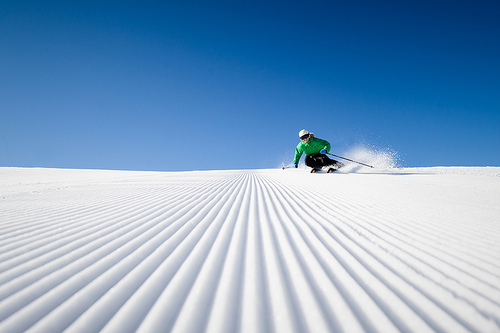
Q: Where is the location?
A: Hillside.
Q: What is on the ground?
A: Snow.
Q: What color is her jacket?
A: Green.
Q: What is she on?
A: Skis.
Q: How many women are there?
A: One.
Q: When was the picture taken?
A: Day time.